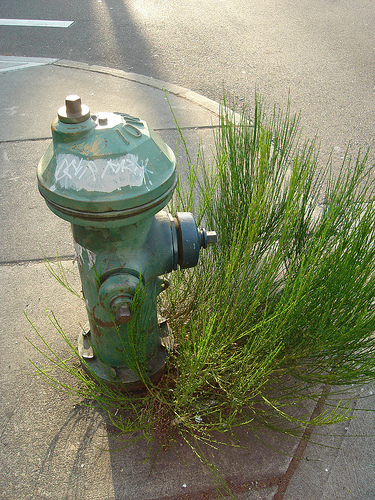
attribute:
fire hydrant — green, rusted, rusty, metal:
[37, 94, 217, 393]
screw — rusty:
[205, 231, 217, 246]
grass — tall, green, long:
[167, 85, 372, 467]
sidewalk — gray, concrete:
[0, 54, 374, 499]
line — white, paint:
[0, 19, 73, 28]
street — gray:
[0, 1, 375, 237]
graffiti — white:
[53, 156, 153, 188]